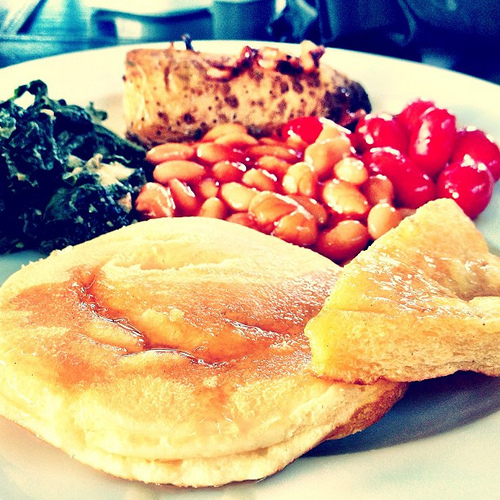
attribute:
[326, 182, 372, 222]
bean — brown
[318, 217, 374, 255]
bean — brown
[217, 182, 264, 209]
bean — brown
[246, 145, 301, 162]
bean — brown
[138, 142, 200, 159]
bean — brown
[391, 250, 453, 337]
biscuit — Soft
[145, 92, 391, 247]
beans — Prepared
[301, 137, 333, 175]
bean — brown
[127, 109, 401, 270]
beans — baked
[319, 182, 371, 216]
bean — brown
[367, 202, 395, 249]
bean — brown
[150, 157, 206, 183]
bean — brown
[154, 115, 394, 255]
beans — baked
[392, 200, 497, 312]
butter bread — Buttered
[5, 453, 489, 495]
plate — round, white